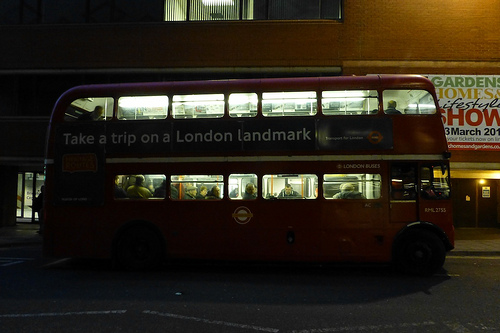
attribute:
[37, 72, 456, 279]
bus — double decker, red, illuminated, two story, lit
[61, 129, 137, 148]
letters — spelling take a trip, white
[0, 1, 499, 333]
scene — in britain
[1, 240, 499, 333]
road — grey, paved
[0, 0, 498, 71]
wall — brick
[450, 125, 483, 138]
month — march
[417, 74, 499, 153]
sign — white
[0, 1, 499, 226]
building — lit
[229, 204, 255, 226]
logo — small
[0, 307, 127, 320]
line — white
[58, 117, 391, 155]
sign — advertising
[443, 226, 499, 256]
sidewalk — existing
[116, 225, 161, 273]
tire — round